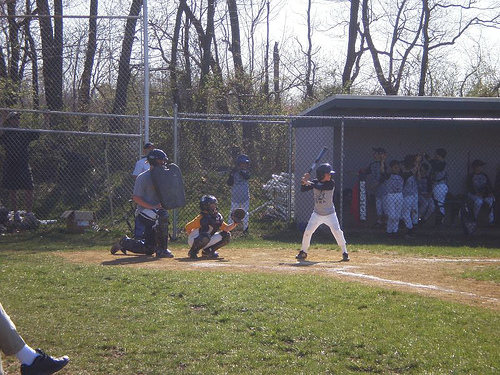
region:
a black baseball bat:
[294, 141, 325, 181]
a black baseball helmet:
[315, 161, 334, 178]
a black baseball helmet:
[199, 195, 217, 212]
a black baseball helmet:
[146, 147, 163, 160]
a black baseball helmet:
[236, 153, 246, 163]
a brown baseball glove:
[232, 207, 247, 222]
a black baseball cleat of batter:
[294, 247, 308, 260]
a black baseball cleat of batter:
[340, 251, 351, 261]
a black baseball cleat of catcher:
[186, 251, 195, 258]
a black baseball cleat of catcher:
[202, 249, 224, 259]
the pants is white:
[259, 194, 383, 271]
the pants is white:
[239, 211, 367, 309]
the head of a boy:
[318, 157, 339, 183]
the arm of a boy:
[309, 175, 336, 193]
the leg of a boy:
[326, 213, 351, 251]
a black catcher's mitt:
[228, 202, 252, 229]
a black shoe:
[20, 342, 77, 373]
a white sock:
[13, 337, 42, 367]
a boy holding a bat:
[291, 140, 354, 266]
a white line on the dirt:
[334, 262, 497, 306]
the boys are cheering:
[362, 138, 456, 249]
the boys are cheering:
[363, 162, 444, 217]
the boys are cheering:
[382, 144, 433, 245]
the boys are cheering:
[389, 115, 461, 306]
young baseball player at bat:
[286, 143, 360, 271]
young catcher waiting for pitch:
[174, 189, 247, 263]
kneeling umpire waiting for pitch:
[113, 141, 188, 263]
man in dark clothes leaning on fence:
[0, 98, 52, 232]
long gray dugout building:
[283, 89, 498, 241]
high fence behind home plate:
[2, 0, 166, 258]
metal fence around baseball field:
[151, 103, 496, 254]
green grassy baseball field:
[0, 223, 499, 374]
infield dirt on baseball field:
[48, 239, 498, 314]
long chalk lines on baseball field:
[318, 246, 497, 314]